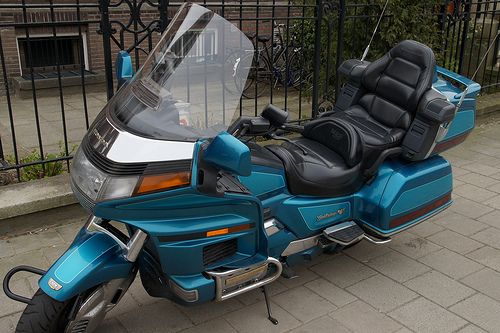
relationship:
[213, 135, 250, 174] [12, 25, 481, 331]
mirror on motorcycle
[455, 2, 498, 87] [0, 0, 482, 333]
antenna on motorcycle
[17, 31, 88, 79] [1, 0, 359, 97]
window on building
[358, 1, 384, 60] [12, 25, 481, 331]
radio antenna on motorcycle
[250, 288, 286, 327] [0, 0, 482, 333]
kickstand on motorcycle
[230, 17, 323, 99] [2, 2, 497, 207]
bicycle parked behind fence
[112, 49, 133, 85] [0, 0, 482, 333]
mirror on motorcycle